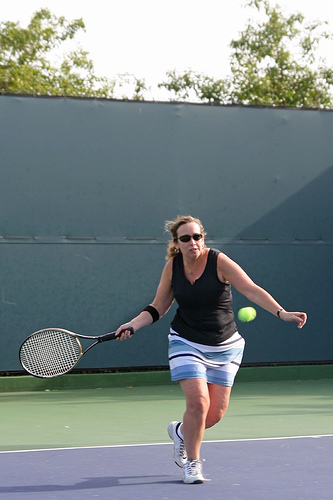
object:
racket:
[14, 326, 135, 381]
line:
[0, 432, 332, 454]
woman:
[115, 215, 308, 483]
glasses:
[175, 233, 202, 242]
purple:
[49, 457, 91, 476]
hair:
[164, 213, 205, 263]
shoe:
[166, 419, 190, 470]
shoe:
[181, 457, 205, 483]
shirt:
[162, 252, 239, 347]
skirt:
[166, 328, 246, 388]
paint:
[0, 437, 332, 499]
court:
[0, 378, 332, 499]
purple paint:
[0, 368, 332, 434]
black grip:
[96, 325, 134, 343]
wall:
[0, 98, 332, 375]